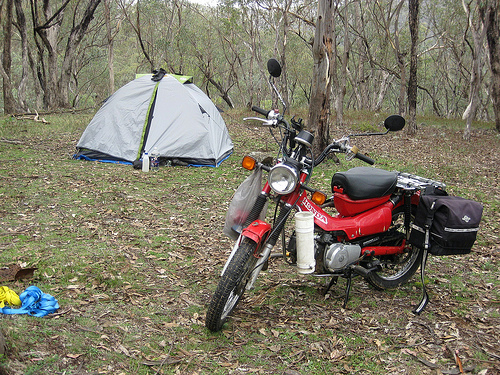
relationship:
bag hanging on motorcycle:
[226, 172, 301, 224] [205, 58, 484, 331]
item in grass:
[20, 284, 60, 317] [1, 120, 499, 372]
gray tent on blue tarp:
[107, 74, 227, 143] [80, 148, 226, 171]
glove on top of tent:
[150, 68, 167, 82] [70, 68, 235, 171]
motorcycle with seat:
[205, 58, 484, 331] [334, 171, 399, 195]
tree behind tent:
[12, 0, 118, 110] [70, 68, 235, 171]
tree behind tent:
[101, 0, 121, 92] [70, 68, 235, 171]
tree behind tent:
[132, 0, 199, 66] [70, 68, 235, 171]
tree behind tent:
[212, 0, 248, 108] [70, 68, 235, 171]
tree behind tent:
[237, 0, 268, 100] [70, 68, 235, 171]